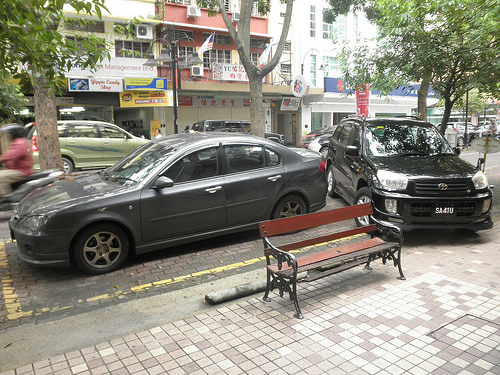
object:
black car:
[324, 117, 495, 236]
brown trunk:
[31, 74, 63, 171]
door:
[278, 114, 284, 139]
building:
[0, 0, 500, 148]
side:
[262, 237, 302, 320]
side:
[369, 214, 408, 279]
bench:
[258, 202, 406, 320]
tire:
[73, 221, 129, 275]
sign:
[212, 62, 265, 82]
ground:
[351, 222, 370, 259]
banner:
[356, 82, 369, 117]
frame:
[158, 0, 272, 84]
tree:
[365, 4, 499, 158]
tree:
[0, 1, 107, 173]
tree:
[202, 0, 309, 142]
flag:
[197, 34, 214, 55]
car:
[186, 119, 287, 147]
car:
[9, 130, 328, 274]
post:
[169, 48, 179, 132]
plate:
[431, 203, 457, 218]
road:
[0, 113, 500, 375]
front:
[372, 169, 494, 235]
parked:
[0, 115, 500, 276]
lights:
[186, 52, 203, 67]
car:
[27, 119, 153, 176]